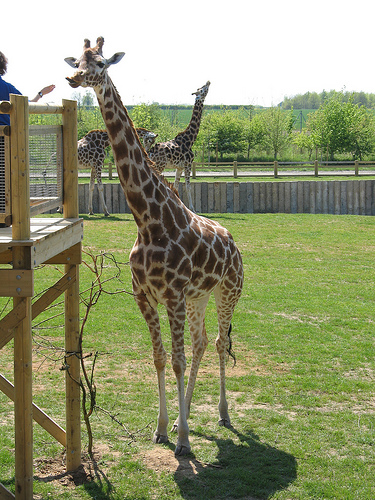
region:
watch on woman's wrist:
[36, 88, 44, 97]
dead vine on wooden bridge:
[34, 227, 135, 485]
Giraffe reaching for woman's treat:
[51, 27, 279, 479]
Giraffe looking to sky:
[172, 70, 216, 175]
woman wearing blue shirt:
[0, 44, 54, 142]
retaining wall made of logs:
[214, 180, 373, 218]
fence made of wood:
[197, 156, 373, 177]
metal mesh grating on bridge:
[22, 122, 71, 211]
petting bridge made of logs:
[0, 81, 88, 498]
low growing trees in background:
[207, 104, 373, 161]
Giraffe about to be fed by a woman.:
[38, 65, 103, 99]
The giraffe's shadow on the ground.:
[168, 425, 313, 498]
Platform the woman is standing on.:
[9, 99, 100, 494]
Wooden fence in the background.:
[232, 178, 373, 217]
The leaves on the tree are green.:
[312, 99, 368, 150]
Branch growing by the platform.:
[55, 297, 123, 468]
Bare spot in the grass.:
[134, 439, 194, 478]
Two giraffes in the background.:
[87, 80, 228, 196]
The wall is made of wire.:
[25, 136, 67, 194]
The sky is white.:
[132, 17, 283, 72]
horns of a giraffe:
[79, 34, 106, 50]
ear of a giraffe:
[106, 51, 127, 66]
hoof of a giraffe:
[168, 442, 195, 459]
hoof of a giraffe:
[148, 427, 171, 446]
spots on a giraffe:
[144, 196, 216, 268]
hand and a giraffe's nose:
[31, 65, 91, 99]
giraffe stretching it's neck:
[164, 73, 245, 156]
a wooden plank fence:
[222, 173, 299, 217]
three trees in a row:
[214, 110, 328, 157]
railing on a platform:
[2, 87, 84, 235]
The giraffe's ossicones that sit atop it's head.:
[80, 35, 105, 50]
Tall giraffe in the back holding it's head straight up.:
[146, 79, 211, 212]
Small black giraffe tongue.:
[64, 75, 74, 83]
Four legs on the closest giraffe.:
[129, 260, 246, 453]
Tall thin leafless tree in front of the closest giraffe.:
[19, 243, 155, 450]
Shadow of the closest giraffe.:
[161, 422, 298, 499]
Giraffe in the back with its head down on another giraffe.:
[41, 125, 157, 218]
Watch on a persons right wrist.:
[35, 90, 44, 99]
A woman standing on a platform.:
[0, 50, 57, 227]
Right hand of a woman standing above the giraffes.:
[40, 83, 57, 94]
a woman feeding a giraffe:
[0, 50, 118, 109]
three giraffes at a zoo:
[61, 35, 259, 473]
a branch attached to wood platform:
[71, 241, 147, 492]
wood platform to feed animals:
[1, 86, 89, 487]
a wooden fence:
[31, 168, 372, 216]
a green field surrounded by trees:
[27, 85, 365, 147]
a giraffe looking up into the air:
[162, 69, 229, 159]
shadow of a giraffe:
[139, 381, 304, 498]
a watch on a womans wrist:
[32, 83, 52, 103]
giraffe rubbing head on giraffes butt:
[131, 121, 169, 161]